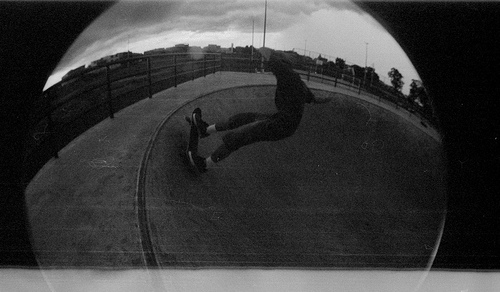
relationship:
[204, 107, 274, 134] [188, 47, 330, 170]
leg on person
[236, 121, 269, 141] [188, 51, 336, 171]
thigh of boy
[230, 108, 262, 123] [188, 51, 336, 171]
thigh of boy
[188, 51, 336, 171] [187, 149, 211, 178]
boy has foot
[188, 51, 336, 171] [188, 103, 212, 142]
boy has foot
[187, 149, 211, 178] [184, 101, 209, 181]
foot on skateboard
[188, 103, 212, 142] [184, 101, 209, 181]
foot on skateboard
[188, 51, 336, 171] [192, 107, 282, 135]
boy has leg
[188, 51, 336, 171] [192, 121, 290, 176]
boy has leg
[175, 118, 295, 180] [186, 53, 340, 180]
leg on person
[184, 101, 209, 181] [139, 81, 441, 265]
skateboard going up a ramp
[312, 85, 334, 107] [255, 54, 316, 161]
arm of boy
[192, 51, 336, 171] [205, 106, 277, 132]
boy has leg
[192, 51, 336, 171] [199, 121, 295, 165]
boy has leg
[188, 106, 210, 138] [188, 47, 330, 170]
foot on person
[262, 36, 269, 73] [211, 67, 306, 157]
arm on boy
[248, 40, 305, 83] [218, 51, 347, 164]
head on boy